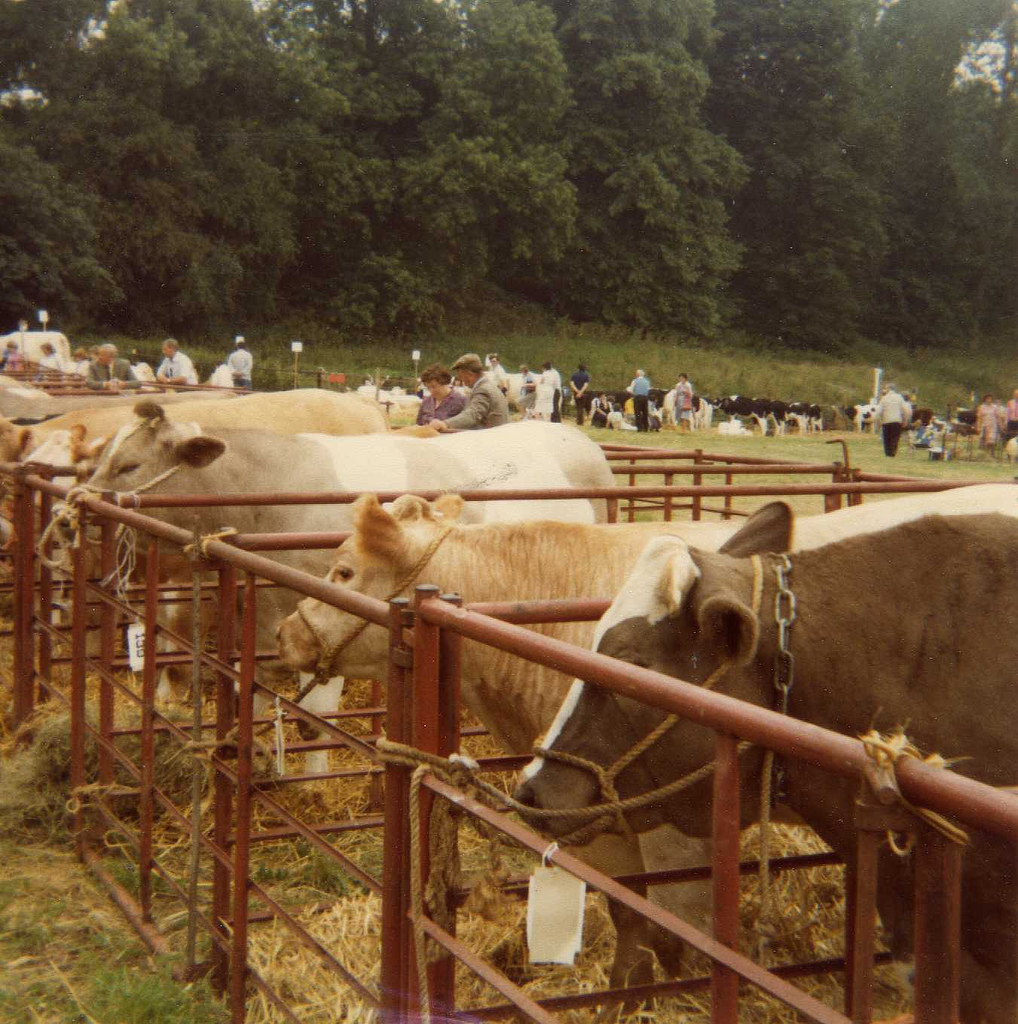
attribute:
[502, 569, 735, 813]
face — white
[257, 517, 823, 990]
cow — light brown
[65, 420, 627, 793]
cow — brown, white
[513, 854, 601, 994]
tag — white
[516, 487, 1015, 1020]
cow — brown, white, dark brown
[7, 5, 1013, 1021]
scene — outdoors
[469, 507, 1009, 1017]
cow — brown, white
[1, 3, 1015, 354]
trees — tall, green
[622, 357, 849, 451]
cows — black, white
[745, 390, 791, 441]
cow — BLACK, WHITE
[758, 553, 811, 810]
collar — CHAIN